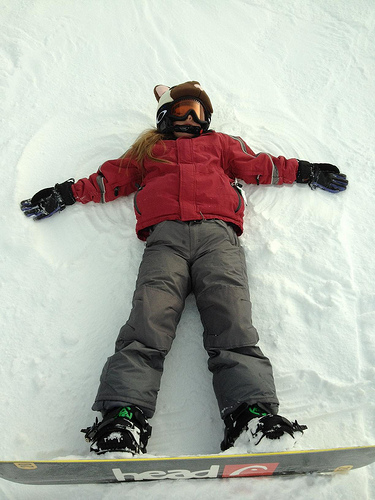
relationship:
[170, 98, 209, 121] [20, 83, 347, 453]
goggles on girl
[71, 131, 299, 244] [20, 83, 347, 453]
jacket on girl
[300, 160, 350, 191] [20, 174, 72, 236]
glove on hand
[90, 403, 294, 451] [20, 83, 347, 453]
shoes on girl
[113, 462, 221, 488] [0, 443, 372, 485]
word on snowboard